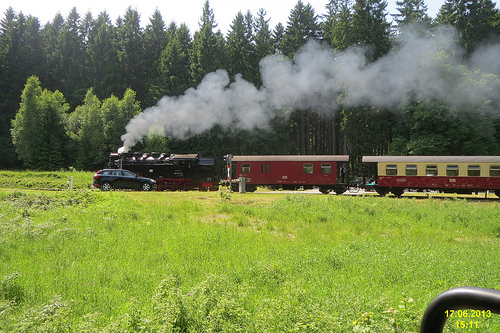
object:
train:
[106, 151, 500, 198]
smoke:
[119, 20, 500, 153]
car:
[92, 168, 156, 191]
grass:
[1, 192, 498, 330]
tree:
[187, 1, 226, 191]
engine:
[108, 152, 220, 191]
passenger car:
[231, 155, 351, 194]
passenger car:
[360, 155, 499, 198]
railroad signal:
[223, 153, 232, 194]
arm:
[220, 179, 236, 184]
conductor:
[340, 166, 347, 183]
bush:
[9, 74, 41, 171]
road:
[35, 186, 500, 204]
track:
[0, 182, 496, 200]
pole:
[420, 286, 499, 332]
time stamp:
[445, 310, 492, 329]